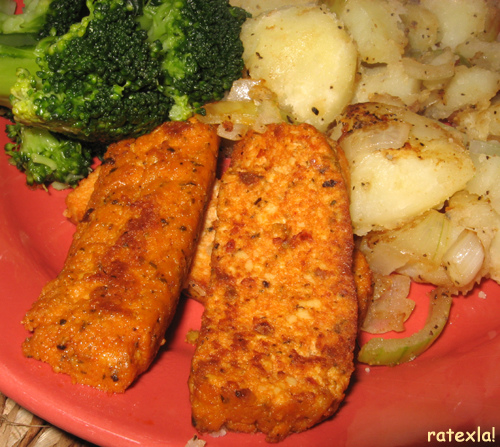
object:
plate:
[390, 322, 499, 447]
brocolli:
[1, 0, 240, 138]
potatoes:
[346, 105, 476, 238]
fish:
[191, 124, 356, 431]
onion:
[363, 334, 434, 366]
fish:
[17, 121, 219, 393]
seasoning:
[250, 233, 259, 239]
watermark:
[423, 427, 494, 444]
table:
[0, 390, 89, 447]